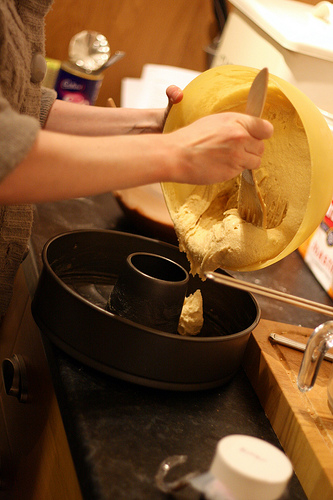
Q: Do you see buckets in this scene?
A: No, there are no buckets.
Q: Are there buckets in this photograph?
A: No, there are no buckets.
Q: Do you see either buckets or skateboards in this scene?
A: No, there are no buckets or skateboards.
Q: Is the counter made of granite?
A: Yes, the counter is made of granite.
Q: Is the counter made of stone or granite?
A: The counter is made of granite.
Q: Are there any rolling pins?
A: No, there are no rolling pins.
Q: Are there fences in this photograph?
A: No, there are no fences.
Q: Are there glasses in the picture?
A: No, there are no glasses.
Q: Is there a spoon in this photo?
A: Yes, there is a spoon.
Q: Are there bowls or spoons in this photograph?
A: Yes, there is a spoon.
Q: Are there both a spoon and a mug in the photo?
A: No, there is a spoon but no mugs.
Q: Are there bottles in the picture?
A: No, there are no bottles.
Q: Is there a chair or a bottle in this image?
A: No, there are no bottles or chairs.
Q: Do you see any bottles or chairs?
A: No, there are no bottles or chairs.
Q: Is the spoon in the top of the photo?
A: Yes, the spoon is in the top of the image.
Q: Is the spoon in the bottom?
A: No, the spoon is in the top of the image.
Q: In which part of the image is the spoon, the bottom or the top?
A: The spoon is in the top of the image.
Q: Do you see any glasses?
A: No, there are no glasses.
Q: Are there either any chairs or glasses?
A: No, there are no glasses or chairs.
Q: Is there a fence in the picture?
A: No, there are no fences.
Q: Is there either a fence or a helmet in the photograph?
A: No, there are no fences or helmets.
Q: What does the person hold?
A: The person holds the mixing bowl.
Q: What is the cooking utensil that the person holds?
A: The cooking utensil is a mixing bowl.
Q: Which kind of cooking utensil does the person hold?
A: The person holds the mixing bowl.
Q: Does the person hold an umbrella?
A: No, the person holds the mixing bowl.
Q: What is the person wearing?
A: The person is wearing a sweater.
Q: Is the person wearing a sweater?
A: Yes, the person is wearing a sweater.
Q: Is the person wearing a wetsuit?
A: No, the person is wearing a sweater.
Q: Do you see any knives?
A: Yes, there is a knife.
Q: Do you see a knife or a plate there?
A: Yes, there is a knife.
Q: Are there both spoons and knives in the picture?
A: Yes, there are both a knife and a spoon.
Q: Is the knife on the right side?
A: Yes, the knife is on the right of the image.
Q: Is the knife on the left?
A: No, the knife is on the right of the image.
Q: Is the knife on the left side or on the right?
A: The knife is on the right of the image.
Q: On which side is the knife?
A: The knife is on the right of the image.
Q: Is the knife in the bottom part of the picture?
A: Yes, the knife is in the bottom of the image.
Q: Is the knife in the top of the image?
A: No, the knife is in the bottom of the image.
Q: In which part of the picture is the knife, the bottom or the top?
A: The knife is in the bottom of the image.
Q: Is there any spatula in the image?
A: Yes, there is a spatula.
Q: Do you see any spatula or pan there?
A: Yes, there is a spatula.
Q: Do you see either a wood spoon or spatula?
A: Yes, there is a wood spatula.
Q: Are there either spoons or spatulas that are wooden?
A: Yes, the spatula is wooden.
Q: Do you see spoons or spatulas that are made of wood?
A: Yes, the spatula is made of wood.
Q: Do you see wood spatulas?
A: Yes, there is a wood spatula.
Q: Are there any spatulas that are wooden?
A: Yes, there is a spatula that is wooden.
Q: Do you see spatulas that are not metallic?
A: Yes, there is a wooden spatula.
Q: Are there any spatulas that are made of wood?
A: Yes, there is a spatula that is made of wood.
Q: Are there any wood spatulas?
A: Yes, there is a spatula that is made of wood.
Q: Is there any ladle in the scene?
A: No, there are no ladles.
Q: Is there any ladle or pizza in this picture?
A: No, there are no ladles or pizzas.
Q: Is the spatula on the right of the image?
A: Yes, the spatula is on the right of the image.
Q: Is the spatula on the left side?
A: No, the spatula is on the right of the image.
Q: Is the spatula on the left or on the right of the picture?
A: The spatula is on the right of the image.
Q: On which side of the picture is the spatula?
A: The spatula is on the right of the image.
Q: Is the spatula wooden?
A: Yes, the spatula is wooden.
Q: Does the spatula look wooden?
A: Yes, the spatula is wooden.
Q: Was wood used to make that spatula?
A: Yes, the spatula is made of wood.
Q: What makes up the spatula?
A: The spatula is made of wood.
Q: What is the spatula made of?
A: The spatula is made of wood.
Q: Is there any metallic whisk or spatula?
A: No, there is a spatula but it is wooden.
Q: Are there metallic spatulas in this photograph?
A: No, there is a spatula but it is wooden.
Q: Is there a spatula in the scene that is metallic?
A: No, there is a spatula but it is wooden.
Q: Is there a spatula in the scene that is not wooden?
A: No, there is a spatula but it is wooden.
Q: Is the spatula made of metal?
A: No, the spatula is made of wood.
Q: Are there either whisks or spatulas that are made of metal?
A: No, there is a spatula but it is made of wood.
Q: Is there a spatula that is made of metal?
A: No, there is a spatula but it is made of wood.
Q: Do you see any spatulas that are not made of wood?
A: No, there is a spatula but it is made of wood.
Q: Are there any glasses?
A: No, there are no glasses.